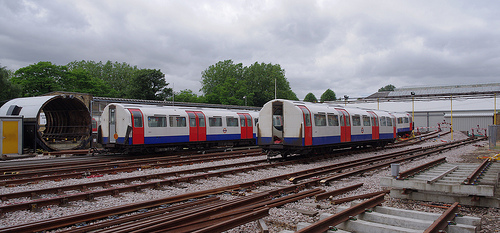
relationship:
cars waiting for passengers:
[254, 99, 414, 162] [434, 152, 484, 210]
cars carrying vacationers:
[254, 99, 414, 162] [317, 117, 337, 126]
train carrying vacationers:
[98, 102, 256, 154] [317, 117, 337, 126]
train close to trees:
[98, 102, 256, 154] [174, 50, 290, 100]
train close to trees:
[98, 102, 256, 154] [4, 48, 193, 115]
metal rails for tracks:
[192, 202, 274, 232] [40, 155, 419, 231]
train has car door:
[94, 101, 261, 157] [127, 108, 145, 145]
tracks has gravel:
[135, 186, 324, 233] [227, 170, 251, 184]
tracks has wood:
[135, 186, 324, 233] [170, 181, 188, 190]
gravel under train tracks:
[361, 169, 388, 191] [0, 125, 499, 232]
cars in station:
[254, 99, 414, 162] [1, 122, 498, 231]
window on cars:
[314, 113, 327, 126] [254, 99, 414, 162]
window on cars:
[352, 116, 361, 126] [254, 99, 414, 162]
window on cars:
[351, 113, 361, 126] [254, 99, 414, 162]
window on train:
[172, 114, 188, 125] [98, 102, 256, 154]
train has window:
[98, 102, 256, 154] [207, 115, 220, 128]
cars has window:
[254, 99, 414, 162] [145, 111, 170, 128]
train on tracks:
[98, 102, 256, 154] [2, 146, 261, 184]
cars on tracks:
[254, 99, 414, 162] [2, 146, 261, 184]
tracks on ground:
[221, 165, 303, 202] [4, 151, 498, 225]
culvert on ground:
[5, 95, 92, 152] [5, 161, 498, 229]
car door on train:
[127, 108, 145, 145] [97, 95, 263, 152]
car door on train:
[185, 110, 207, 141] [99, 105, 261, 153]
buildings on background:
[396, 76, 491, 117] [6, 67, 497, 99]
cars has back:
[254, 99, 414, 162] [258, 98, 300, 137]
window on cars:
[145, 108, 165, 135] [254, 99, 414, 162]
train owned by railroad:
[98, 102, 256, 154] [2, 149, 309, 231]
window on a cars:
[311, 109, 326, 126] [254, 99, 414, 162]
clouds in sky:
[345, 4, 460, 59] [0, 0, 498, 102]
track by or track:
[3, 150, 265, 216] [0, 137, 485, 231]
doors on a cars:
[298, 122, 400, 142] [254, 99, 414, 162]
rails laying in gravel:
[319, 176, 368, 200] [343, 170, 401, 189]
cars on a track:
[249, 95, 420, 156] [3, 126, 496, 231]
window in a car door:
[129, 107, 144, 132] [127, 105, 146, 145]